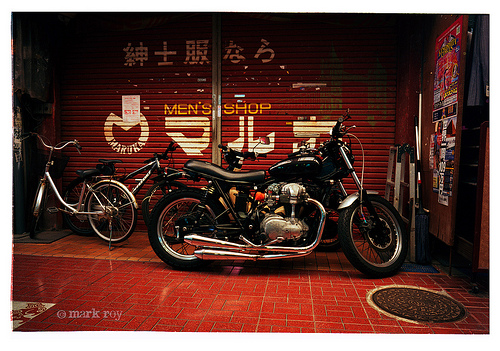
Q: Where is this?
A: This is at the garage.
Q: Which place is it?
A: It is a garage.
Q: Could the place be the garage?
A: Yes, it is the garage.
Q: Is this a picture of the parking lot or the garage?
A: It is showing the garage.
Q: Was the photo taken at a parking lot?
A: No, the picture was taken in a garage.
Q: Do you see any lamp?
A: No, there are no lamps.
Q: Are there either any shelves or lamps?
A: No, there are no lamps or shelves.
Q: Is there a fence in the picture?
A: No, there are no fences.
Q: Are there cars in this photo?
A: No, there are no cars.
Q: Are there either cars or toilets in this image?
A: No, there are no cars or toilets.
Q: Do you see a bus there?
A: No, there are no buses.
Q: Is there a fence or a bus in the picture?
A: No, there are no buses or fences.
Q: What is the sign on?
A: The sign is on the wall.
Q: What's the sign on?
A: The sign is on the wall.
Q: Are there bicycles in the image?
A: Yes, there is a bicycle.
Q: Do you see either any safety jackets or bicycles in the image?
A: Yes, there is a bicycle.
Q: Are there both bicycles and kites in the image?
A: No, there is a bicycle but no kites.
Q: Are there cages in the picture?
A: No, there are no cages.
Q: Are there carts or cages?
A: No, there are no cages or carts.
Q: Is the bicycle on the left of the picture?
A: Yes, the bicycle is on the left of the image.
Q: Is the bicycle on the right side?
A: No, the bicycle is on the left of the image.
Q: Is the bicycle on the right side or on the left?
A: The bicycle is on the left of the image.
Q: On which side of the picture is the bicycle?
A: The bicycle is on the left of the image.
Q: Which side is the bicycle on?
A: The bicycle is on the left of the image.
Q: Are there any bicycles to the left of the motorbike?
A: Yes, there is a bicycle to the left of the motorbike.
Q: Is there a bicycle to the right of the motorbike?
A: No, the bicycle is to the left of the motorbike.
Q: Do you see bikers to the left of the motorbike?
A: No, there is a bicycle to the left of the motorbike.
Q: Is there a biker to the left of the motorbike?
A: No, there is a bicycle to the left of the motorbike.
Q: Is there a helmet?
A: No, there are no helmets.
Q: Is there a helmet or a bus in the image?
A: No, there are no helmets or buses.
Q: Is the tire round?
A: Yes, the tire is round.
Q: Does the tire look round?
A: Yes, the tire is round.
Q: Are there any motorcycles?
A: Yes, there is a motorcycle.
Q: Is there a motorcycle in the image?
A: Yes, there is a motorcycle.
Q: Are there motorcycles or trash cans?
A: Yes, there is a motorcycle.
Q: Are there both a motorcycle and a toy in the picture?
A: No, there is a motorcycle but no toys.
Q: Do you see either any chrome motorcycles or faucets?
A: Yes, there is a chrome motorcycle.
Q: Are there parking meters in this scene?
A: No, there are no parking meters.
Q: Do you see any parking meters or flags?
A: No, there are no parking meters or flags.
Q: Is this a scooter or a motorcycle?
A: This is a motorcycle.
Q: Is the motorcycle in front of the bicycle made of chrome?
A: Yes, the motorbike is made of chrome.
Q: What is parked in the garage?
A: The motorcycle is parked in the garage.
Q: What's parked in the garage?
A: The motorcycle is parked in the garage.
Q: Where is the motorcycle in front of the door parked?
A: The motorcycle is parked in the garage.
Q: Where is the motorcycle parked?
A: The motorcycle is parked in the garage.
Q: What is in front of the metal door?
A: The motorcycle is in front of the door.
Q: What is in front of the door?
A: The motorcycle is in front of the door.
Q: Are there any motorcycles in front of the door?
A: Yes, there is a motorcycle in front of the door.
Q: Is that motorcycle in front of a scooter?
A: No, the motorcycle is in front of the bicycle.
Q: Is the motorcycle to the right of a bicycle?
A: Yes, the motorcycle is to the right of a bicycle.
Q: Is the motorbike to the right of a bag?
A: No, the motorbike is to the right of a bicycle.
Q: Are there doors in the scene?
A: Yes, there is a door.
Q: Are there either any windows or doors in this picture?
A: Yes, there is a door.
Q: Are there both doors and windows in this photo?
A: No, there is a door but no windows.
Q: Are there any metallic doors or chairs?
A: Yes, there is a metal door.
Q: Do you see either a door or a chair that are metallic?
A: Yes, the door is metallic.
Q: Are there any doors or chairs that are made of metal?
A: Yes, the door is made of metal.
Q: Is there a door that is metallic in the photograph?
A: Yes, there is a metal door.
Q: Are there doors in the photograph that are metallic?
A: Yes, there is a door that is metallic.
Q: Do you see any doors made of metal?
A: Yes, there is a door that is made of metal.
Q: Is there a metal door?
A: Yes, there is a door that is made of metal.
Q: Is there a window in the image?
A: No, there are no windows.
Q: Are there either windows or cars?
A: No, there are no windows or cars.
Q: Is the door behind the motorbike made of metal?
A: Yes, the door is made of metal.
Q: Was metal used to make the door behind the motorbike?
A: Yes, the door is made of metal.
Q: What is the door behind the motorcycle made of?
A: The door is made of metal.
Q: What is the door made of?
A: The door is made of metal.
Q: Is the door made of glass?
A: No, the door is made of metal.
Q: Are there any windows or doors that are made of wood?
A: No, there is a door but it is made of metal.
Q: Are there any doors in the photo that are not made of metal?
A: No, there is a door but it is made of metal.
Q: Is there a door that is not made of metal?
A: No, there is a door but it is made of metal.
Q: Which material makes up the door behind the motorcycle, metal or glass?
A: The door is made of metal.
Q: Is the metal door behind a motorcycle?
A: Yes, the door is behind a motorcycle.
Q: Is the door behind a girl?
A: No, the door is behind a motorcycle.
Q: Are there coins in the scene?
A: No, there are no coins.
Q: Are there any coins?
A: No, there are no coins.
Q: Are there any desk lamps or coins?
A: No, there are no coins or desk lamps.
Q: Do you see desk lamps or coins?
A: No, there are no coins or desk lamps.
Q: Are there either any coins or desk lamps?
A: No, there are no coins or desk lamps.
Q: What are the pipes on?
A: The pipes are on the motorbike.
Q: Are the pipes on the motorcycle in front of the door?
A: Yes, the pipes are on the motorcycle.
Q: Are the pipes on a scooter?
A: No, the pipes are on the motorcycle.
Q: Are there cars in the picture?
A: No, there are no cars.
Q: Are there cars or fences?
A: No, there are no cars or fences.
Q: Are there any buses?
A: No, there are no buses.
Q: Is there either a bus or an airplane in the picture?
A: No, there are no buses or airplanes.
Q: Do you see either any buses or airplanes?
A: No, there are no buses or airplanes.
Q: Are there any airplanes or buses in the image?
A: No, there are no buses or airplanes.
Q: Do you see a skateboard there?
A: No, there are no skateboards.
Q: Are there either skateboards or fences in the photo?
A: No, there are no skateboards or fences.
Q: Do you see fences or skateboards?
A: No, there are no skateboards or fences.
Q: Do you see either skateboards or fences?
A: No, there are no skateboards or fences.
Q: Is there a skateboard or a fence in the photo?
A: No, there are no skateboards or fences.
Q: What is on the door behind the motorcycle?
A: The symbol is on the door.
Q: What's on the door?
A: The symbol is on the door.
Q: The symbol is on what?
A: The symbol is on the door.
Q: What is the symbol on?
A: The symbol is on the door.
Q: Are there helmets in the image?
A: No, there are no helmets.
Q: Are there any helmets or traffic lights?
A: No, there are no helmets or traffic lights.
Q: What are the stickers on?
A: The stickers are on the wall.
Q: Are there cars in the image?
A: No, there are no cars.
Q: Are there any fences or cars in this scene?
A: No, there are no cars or fences.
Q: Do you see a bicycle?
A: Yes, there is a bicycle.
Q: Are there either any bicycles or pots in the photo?
A: Yes, there is a bicycle.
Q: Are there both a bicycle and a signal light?
A: No, there is a bicycle but no traffic lights.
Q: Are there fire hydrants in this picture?
A: No, there are no fire hydrants.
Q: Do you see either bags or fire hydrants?
A: No, there are no fire hydrants or bags.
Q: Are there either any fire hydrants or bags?
A: No, there are no fire hydrants or bags.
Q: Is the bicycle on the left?
A: Yes, the bicycle is on the left of the image.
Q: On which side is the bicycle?
A: The bicycle is on the left of the image.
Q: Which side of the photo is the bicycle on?
A: The bicycle is on the left of the image.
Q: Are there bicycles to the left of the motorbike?
A: Yes, there is a bicycle to the left of the motorbike.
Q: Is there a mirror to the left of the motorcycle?
A: No, there is a bicycle to the left of the motorcycle.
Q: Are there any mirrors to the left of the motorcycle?
A: No, there is a bicycle to the left of the motorcycle.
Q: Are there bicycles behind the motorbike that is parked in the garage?
A: Yes, there is a bicycle behind the motorcycle.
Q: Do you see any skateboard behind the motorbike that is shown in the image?
A: No, there is a bicycle behind the motorbike.